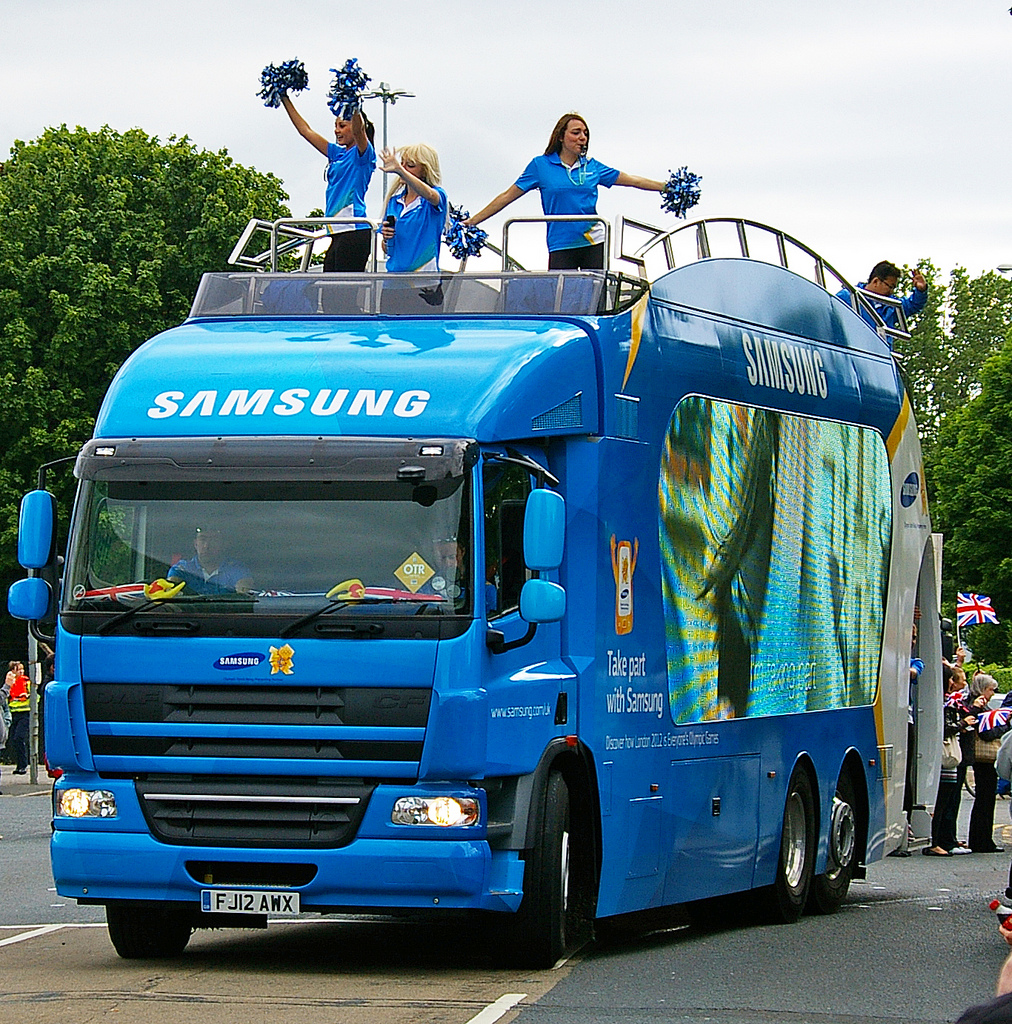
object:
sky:
[699, 0, 1002, 208]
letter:
[178, 379, 219, 424]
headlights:
[425, 778, 484, 831]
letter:
[810, 347, 834, 403]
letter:
[146, 384, 182, 420]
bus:
[6, 184, 941, 967]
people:
[451, 51, 688, 273]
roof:
[198, 263, 596, 320]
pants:
[923, 761, 968, 846]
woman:
[272, 82, 378, 276]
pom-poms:
[255, 57, 313, 106]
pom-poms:
[324, 55, 368, 123]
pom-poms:
[322, 49, 373, 121]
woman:
[459, 110, 683, 266]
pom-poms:
[444, 194, 491, 260]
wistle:
[578, 145, 589, 165]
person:
[919, 662, 977, 857]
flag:
[952, 584, 999, 672]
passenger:
[163, 507, 260, 606]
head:
[184, 504, 231, 564]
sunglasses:
[187, 518, 224, 528]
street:
[698, 921, 1011, 1013]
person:
[253, 51, 388, 275]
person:
[372, 143, 456, 279]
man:
[405, 529, 502, 619]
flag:
[954, 701, 1011, 737]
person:
[957, 674, 1012, 845]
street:
[0, 951, 987, 1023]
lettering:
[142, 381, 434, 423]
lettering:
[736, 328, 833, 405]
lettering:
[604, 647, 653, 684]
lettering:
[603, 685, 666, 720]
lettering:
[603, 730, 721, 752]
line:
[459, 983, 538, 1023]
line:
[258, 911, 358, 927]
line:
[0, 914, 111, 931]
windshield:
[70, 471, 476, 640]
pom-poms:
[657, 156, 705, 221]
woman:
[363, 139, 455, 281]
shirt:
[512, 147, 622, 254]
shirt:
[372, 184, 455, 269]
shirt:
[311, 139, 373, 230]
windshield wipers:
[274, 588, 448, 642]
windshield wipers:
[86, 584, 268, 630]